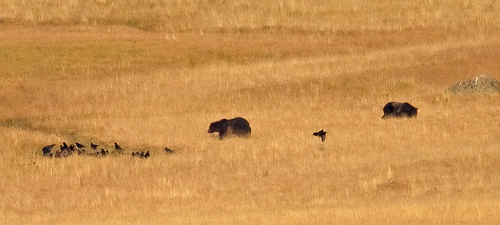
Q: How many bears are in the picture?
A: Two.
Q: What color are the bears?
A: Black.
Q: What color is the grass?
A: Yellow.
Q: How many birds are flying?
A: One.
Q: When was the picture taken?
A: Daytime.